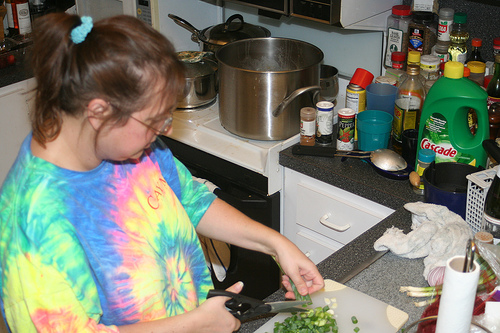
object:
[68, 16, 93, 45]
scrunchie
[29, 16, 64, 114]
hair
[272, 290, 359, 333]
vegetables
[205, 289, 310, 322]
scissors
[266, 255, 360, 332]
food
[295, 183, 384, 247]
drawer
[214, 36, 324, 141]
pot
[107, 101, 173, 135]
eyeglasses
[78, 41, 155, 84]
hair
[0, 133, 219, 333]
shirt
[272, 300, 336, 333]
onions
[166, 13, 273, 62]
pots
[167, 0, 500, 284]
kitchen supplies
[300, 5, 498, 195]
food items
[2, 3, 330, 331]
lady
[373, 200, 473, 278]
dish rag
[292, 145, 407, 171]
metal spoon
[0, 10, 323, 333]
woman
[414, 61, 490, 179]
large container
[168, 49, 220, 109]
pots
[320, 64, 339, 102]
stove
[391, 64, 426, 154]
bottle/olive oil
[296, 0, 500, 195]
spices/condiments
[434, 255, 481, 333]
paper towel/holder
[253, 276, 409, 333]
cutting board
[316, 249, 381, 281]
grey countertops